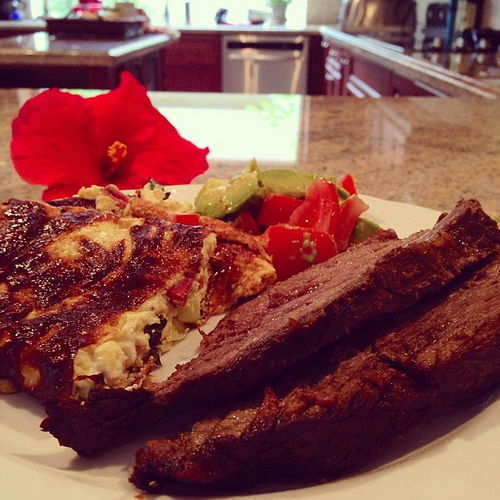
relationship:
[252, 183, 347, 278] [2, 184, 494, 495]
tomato on plate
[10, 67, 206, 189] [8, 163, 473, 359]
flower by plate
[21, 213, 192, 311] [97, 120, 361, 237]
casserole with peppers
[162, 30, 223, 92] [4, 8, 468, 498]
cabinet in kitchen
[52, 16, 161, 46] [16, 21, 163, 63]
basket on counter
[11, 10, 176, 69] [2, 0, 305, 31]
island near counter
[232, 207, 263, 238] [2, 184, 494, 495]
tomato on plate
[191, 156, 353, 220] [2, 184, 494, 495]
avocado on plate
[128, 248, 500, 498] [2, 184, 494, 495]
meat on plate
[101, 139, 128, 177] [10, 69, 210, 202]
stem of flower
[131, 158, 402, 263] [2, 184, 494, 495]
salad on a plate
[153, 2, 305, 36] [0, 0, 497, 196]
window in kitchen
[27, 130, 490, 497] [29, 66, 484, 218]
table made of granite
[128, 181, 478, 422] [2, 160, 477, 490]
meat on dish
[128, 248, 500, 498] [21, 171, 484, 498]
meat on dish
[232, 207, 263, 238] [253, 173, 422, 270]
tomato on plate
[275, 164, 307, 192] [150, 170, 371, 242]
avocado on plate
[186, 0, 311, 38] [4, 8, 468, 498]
window letting light kitchen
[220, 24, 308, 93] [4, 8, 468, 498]
stove in kitchen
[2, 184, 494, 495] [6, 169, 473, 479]
plate on food